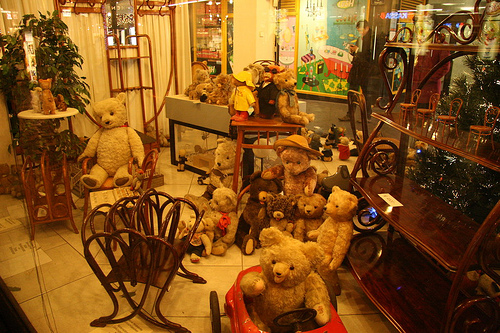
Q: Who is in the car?
A: Teddy bear.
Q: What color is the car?
A: Red.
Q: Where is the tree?
A: Behind the shelf.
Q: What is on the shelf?
A: Small chairs.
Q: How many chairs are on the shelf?
A: Four.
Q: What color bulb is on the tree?
A: Blue.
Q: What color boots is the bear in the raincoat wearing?
A: Red.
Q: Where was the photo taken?
A: At the toy store.